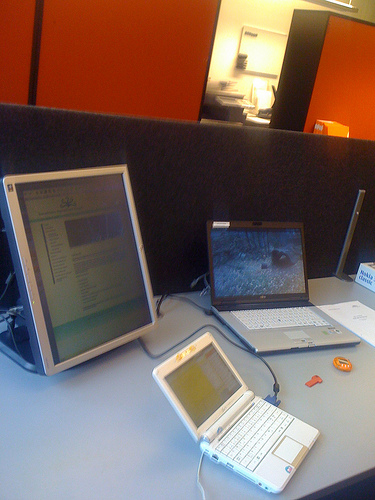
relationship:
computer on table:
[150, 335, 319, 492] [0, 270, 374, 500]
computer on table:
[2, 160, 158, 374] [0, 270, 374, 500]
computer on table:
[205, 219, 361, 353] [0, 270, 374, 500]